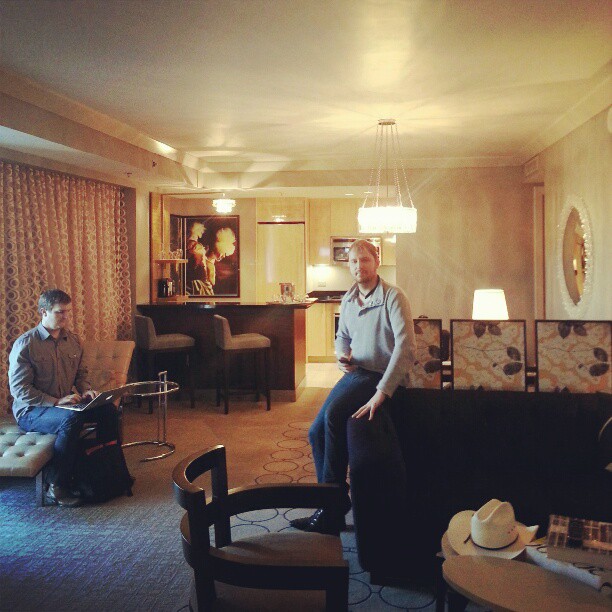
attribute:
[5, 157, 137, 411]
curtain — large, decorative